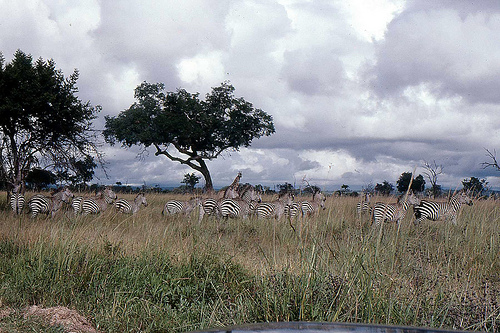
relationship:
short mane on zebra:
[452, 188, 463, 200] [408, 187, 475, 228]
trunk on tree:
[151, 142, 230, 193] [102, 79, 277, 190]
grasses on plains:
[9, 219, 495, 331] [15, 155, 499, 325]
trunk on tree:
[159, 143, 222, 188] [102, 79, 277, 190]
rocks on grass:
[5, 291, 114, 331] [7, 224, 474, 310]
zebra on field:
[413, 190, 473, 230] [0, 192, 500, 332]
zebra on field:
[361, 197, 443, 233] [0, 192, 500, 332]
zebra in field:
[413, 190, 473, 230] [0, 192, 500, 332]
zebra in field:
[254, 191, 294, 221] [3, 181, 496, 329]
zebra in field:
[254, 191, 294, 221] [0, 192, 500, 332]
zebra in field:
[289, 180, 316, 226] [0, 192, 500, 332]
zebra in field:
[361, 197, 443, 233] [0, 192, 500, 332]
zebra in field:
[81, 189, 119, 216] [0, 192, 500, 332]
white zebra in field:
[114, 191, 148, 218] [0, 192, 500, 332]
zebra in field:
[413, 190, 473, 230] [182, 185, 414, 292]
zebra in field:
[215, 183, 261, 220] [0, 192, 500, 332]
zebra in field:
[28, 185, 75, 221] [0, 192, 500, 332]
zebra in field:
[251, 186, 311, 221] [0, 192, 500, 332]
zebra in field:
[349, 178, 372, 220] [182, 226, 354, 296]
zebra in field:
[361, 197, 443, 233] [81, 136, 400, 267]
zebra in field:
[219, 199, 261, 229] [43, 101, 367, 286]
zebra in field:
[413, 190, 473, 230] [43, 101, 367, 286]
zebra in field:
[361, 197, 443, 233] [43, 101, 367, 286]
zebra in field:
[83, 189, 120, 215] [43, 101, 367, 286]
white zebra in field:
[114, 191, 148, 218] [43, 101, 367, 286]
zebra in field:
[12, 186, 28, 212] [43, 101, 367, 286]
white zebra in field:
[114, 191, 148, 218] [63, 102, 396, 272]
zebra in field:
[288, 186, 326, 231] [61, 174, 392, 321]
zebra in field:
[409, 189, 475, 219] [0, 192, 500, 332]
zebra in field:
[288, 186, 326, 231] [0, 192, 500, 332]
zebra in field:
[219, 191, 262, 227] [0, 192, 500, 332]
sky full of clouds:
[1, 0, 499, 190] [2, 0, 499, 186]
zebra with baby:
[361, 197, 443, 233] [366, 186, 418, 236]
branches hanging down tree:
[2, 110, 104, 198] [1, 47, 93, 220]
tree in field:
[43, 62, 278, 168] [0, 192, 500, 332]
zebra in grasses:
[8, 186, 26, 216] [1, 194, 491, 331]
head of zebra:
[442, 180, 483, 227] [383, 174, 483, 259]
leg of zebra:
[220, 213, 227, 238] [213, 187, 239, 234]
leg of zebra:
[214, 213, 221, 237] [213, 187, 239, 234]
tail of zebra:
[17, 198, 30, 215] [26, 189, 73, 221]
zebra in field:
[215, 183, 262, 230] [0, 192, 500, 332]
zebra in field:
[199, 184, 240, 221] [0, 192, 500, 332]